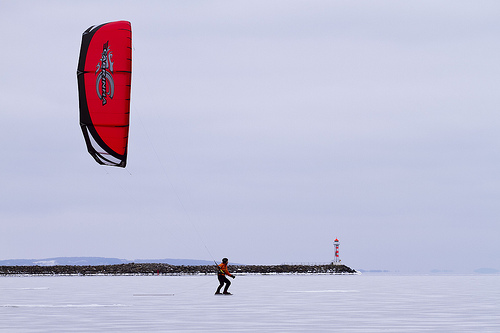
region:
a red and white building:
[329, 235, 344, 264]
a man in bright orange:
[211, 256, 242, 301]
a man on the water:
[214, 256, 236, 297]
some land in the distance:
[8, 245, 213, 267]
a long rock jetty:
[13, 261, 365, 279]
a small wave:
[13, 297, 122, 312]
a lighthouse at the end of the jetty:
[324, 235, 358, 275]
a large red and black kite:
[76, 16, 134, 168]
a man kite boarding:
[76, 19, 239, 299]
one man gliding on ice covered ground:
[211, 254, 238, 294]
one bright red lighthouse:
[331, 235, 347, 268]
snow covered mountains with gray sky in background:
[1, 251, 131, 266]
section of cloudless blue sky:
[43, 180, 311, 244]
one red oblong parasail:
[71, 15, 136, 169]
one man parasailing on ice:
[71, 15, 238, 296]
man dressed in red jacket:
[216, 252, 237, 299]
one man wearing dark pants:
[211, 255, 235, 299]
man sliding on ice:
[151, 257, 253, 305]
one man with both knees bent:
[214, 256, 236, 295]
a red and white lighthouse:
[328, 233, 343, 265]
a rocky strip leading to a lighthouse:
[6, 258, 358, 283]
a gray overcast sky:
[152, 102, 449, 224]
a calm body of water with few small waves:
[55, 281, 407, 330]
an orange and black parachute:
[70, 10, 144, 170]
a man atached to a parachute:
[209, 254, 236, 298]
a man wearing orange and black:
[210, 252, 232, 320]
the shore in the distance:
[6, 249, 245, 278]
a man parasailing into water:
[71, 27, 257, 309]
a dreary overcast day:
[36, 10, 439, 302]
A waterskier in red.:
[210, 256, 237, 296]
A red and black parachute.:
[77, 20, 133, 168]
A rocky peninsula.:
[0, 260, 355, 276]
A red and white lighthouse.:
[332, 235, 342, 262]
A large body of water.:
[0, 272, 498, 328]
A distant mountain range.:
[0, 255, 243, 268]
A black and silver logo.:
[91, 40, 117, 103]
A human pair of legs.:
[215, 275, 232, 293]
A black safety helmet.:
[220, 255, 230, 265]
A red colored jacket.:
[214, 263, 234, 277]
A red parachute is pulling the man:
[74, 18, 238, 296]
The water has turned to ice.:
[0, 268, 499, 331]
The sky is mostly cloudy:
[0, 1, 496, 278]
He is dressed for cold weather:
[213, 258, 235, 296]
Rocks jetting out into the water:
[2, 262, 365, 279]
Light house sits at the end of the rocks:
[329, 235, 356, 273]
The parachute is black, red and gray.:
[78, 17, 140, 173]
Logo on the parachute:
[93, 40, 121, 105]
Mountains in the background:
[3, 254, 259, 271]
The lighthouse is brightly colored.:
[333, 236, 344, 265]